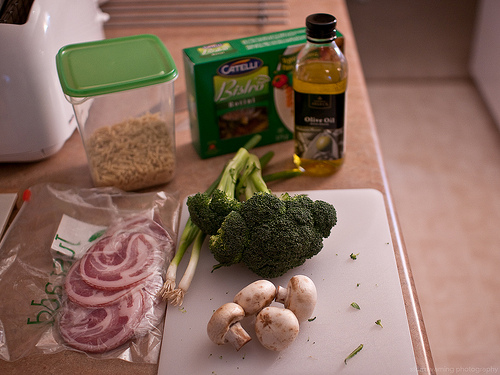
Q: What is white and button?
A: The mushrooms.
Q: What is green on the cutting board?
A: Broccoli.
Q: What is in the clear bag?
A: The meat.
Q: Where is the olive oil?
A: On the counter.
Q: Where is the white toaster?
A: On the counter.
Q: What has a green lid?
A: The plastic container.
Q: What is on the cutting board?
A: Food.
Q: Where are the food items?
A: On the counter.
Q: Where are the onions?
A: In the bag.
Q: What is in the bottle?
A: Olive oil.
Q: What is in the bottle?
A: Olive oil.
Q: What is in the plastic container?
A: Pasta.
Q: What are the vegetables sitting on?
A: Cutting board.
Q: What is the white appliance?
A: Toaster.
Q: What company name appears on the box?
A: Catelli.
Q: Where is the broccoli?
A: On the cutting board.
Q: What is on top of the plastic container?
A: Lid.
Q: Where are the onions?
A: Cutting board.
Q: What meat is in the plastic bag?
A: Bacon.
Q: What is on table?
A: Toaster.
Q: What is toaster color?
A: White.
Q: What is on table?
A: Cutting board.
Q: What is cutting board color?
A: White.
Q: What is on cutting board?
A: Mushrooms.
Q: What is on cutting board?
A: Vegetables.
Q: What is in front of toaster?
A: Clear container.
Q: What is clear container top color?
A: Green.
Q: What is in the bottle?
A: Olive oil.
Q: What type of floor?
A: Tile floor.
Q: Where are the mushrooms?
A: On the cutting board.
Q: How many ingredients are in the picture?
A: 7.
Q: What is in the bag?
A: Onions.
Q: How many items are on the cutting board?
A: Three.